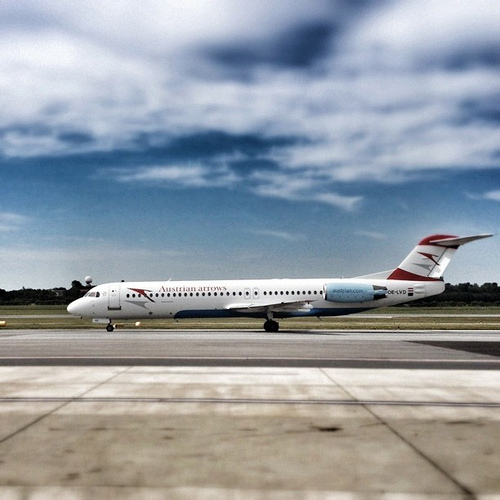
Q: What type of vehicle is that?
A: Airplane.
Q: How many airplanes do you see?
A: One.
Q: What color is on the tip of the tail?
A: Red.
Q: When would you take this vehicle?
A: Trip.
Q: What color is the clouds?
A: White.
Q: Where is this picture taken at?
A: Airport.